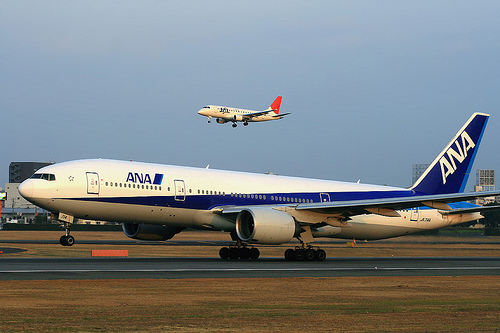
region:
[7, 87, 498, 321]
an airport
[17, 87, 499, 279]
two planes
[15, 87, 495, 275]
two passenger jets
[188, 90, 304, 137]
a plane is in the air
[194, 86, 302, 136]
a plane coming in for landing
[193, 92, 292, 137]
the landing gear on the plane is down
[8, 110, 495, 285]
the plane on the runway is taking off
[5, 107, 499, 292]
the front tires on the plane have left the tarmac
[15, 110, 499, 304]
a white and blue plane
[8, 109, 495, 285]
a passenger plane is taking off from the runway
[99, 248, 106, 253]
orange line is spotted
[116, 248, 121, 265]
orange line is spotted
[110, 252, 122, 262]
orange line is spotted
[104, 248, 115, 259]
orange line is spotted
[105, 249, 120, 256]
orange line is spotted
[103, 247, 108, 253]
orange line is spotted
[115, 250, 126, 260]
orange line is spotted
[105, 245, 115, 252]
orange line is spotted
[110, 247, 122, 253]
orange line is spotted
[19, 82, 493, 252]
big white and blue plane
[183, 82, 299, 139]
plane with red tail flying in the sky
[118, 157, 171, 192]
ANA written on the side of the plane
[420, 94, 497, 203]
ANA on tail end of plane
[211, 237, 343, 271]
back black plane tires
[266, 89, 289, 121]
red tail end of plane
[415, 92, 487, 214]
blue tail end of plane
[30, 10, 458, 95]
pretty blue sky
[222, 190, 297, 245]
right side plane engine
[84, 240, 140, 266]
red rectangle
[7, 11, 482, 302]
pictures of a runway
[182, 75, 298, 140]
a plane taking off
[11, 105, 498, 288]
this plane is landing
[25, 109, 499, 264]
the airplane is blue and white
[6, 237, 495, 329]
the runway has flat grass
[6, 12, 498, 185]
the sky appears clear and blue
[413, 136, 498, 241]
buildings in the background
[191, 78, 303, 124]
this planeis red and white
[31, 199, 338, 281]
landing gear is down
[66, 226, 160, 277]
orange ground equipment to assist with flight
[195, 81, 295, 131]
red and white airplane in sky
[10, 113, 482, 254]
blue and white airplane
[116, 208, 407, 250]
two get engines on plane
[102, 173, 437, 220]
passenger windows on plane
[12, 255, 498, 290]
paved runway with white line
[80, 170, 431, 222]
four doors on the side of the plane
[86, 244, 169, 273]
orange barrier next to runway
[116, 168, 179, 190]
blue letters ANA on white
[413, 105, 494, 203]
white letters ANA on blue tail fin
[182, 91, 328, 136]
jet plane landing